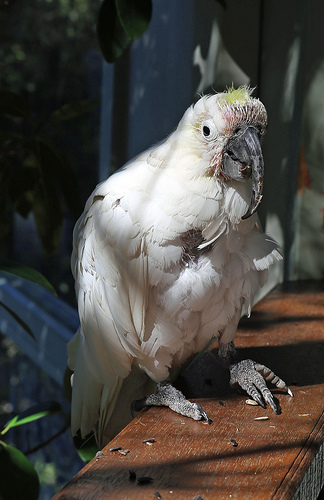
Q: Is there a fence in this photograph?
A: No, there are no fences.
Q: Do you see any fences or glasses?
A: No, there are no fences or glasses.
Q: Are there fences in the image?
A: No, there are no fences.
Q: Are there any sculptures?
A: No, there are no sculptures.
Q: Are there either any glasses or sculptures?
A: No, there are no sculptures or glasses.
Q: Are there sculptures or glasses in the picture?
A: No, there are no sculptures or glasses.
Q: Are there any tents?
A: No, there are no tents.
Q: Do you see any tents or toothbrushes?
A: No, there are no tents or toothbrushes.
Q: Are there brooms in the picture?
A: No, there are no brooms.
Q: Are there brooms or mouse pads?
A: No, there are no brooms or mouse pads.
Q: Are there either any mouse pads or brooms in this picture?
A: No, there are no brooms or mouse pads.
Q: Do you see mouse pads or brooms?
A: No, there are no brooms or mouse pads.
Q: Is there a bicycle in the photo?
A: No, there are no bicycles.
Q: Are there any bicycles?
A: No, there are no bicycles.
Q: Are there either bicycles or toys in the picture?
A: No, there are no bicycles or toys.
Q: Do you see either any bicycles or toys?
A: No, there are no bicycles or toys.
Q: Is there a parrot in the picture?
A: Yes, there is a parrot.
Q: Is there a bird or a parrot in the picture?
A: Yes, there is a parrot.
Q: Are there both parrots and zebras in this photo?
A: No, there is a parrot but no zebras.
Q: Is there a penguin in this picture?
A: No, there are no penguins.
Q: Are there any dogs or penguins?
A: No, there are no penguins or dogs.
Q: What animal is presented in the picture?
A: The animal is a parrot.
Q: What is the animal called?
A: The animal is a parrot.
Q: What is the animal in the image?
A: The animal is a parrot.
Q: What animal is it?
A: The animal is a parrot.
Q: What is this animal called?
A: This is a parrot.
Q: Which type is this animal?
A: This is a parrot.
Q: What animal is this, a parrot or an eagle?
A: This is a parrot.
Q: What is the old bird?
A: The bird is a parrot.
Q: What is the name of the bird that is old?
A: The bird is a parrot.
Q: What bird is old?
A: The bird is a parrot.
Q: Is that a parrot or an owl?
A: That is a parrot.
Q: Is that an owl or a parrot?
A: That is a parrot.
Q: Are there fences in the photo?
A: No, there are no fences.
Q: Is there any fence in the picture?
A: No, there are no fences.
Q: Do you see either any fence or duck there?
A: No, there are no fences or ducks.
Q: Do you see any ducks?
A: No, there are no ducks.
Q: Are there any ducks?
A: No, there are no ducks.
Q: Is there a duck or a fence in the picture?
A: No, there are no ducks or fences.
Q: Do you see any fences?
A: No, there are no fences.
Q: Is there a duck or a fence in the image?
A: No, there are no fences or ducks.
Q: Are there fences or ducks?
A: No, there are no fences or ducks.